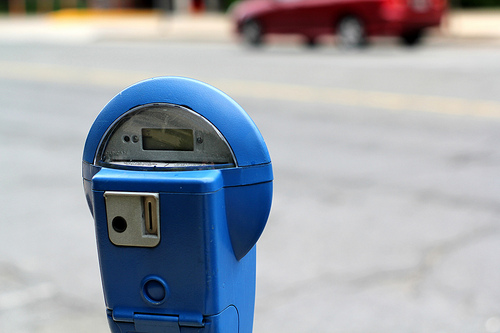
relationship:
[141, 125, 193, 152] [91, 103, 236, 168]
meter screen behind glass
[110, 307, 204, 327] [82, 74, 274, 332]
hinges on parking meter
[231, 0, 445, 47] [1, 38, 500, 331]
car on street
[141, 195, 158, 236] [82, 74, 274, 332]
coin slot on parking meter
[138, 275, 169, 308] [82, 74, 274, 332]
round circle on parking meter